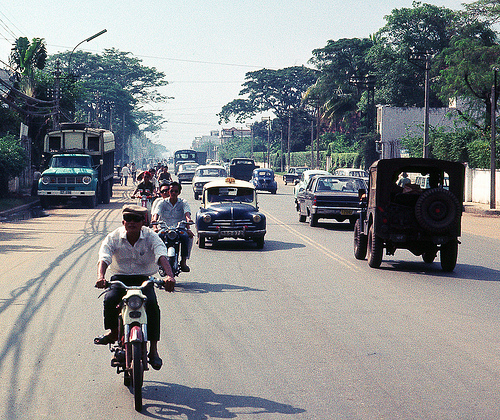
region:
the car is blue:
[220, 206, 236, 216]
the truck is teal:
[60, 165, 80, 170]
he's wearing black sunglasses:
[120, 210, 140, 222]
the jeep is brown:
[367, 190, 377, 200]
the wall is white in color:
[475, 175, 485, 190]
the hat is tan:
[120, 205, 140, 215]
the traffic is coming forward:
[112, 166, 238, 376]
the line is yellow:
[298, 227, 320, 249]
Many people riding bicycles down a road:
[92, 159, 200, 416]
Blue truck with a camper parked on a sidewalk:
[30, 126, 115, 205]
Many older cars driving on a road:
[171, 145, 473, 277]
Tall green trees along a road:
[12, 4, 492, 171]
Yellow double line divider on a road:
[250, 202, 369, 281]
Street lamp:
[64, 22, 112, 54]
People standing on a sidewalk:
[118, 156, 140, 183]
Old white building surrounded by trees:
[372, 99, 497, 151]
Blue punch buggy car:
[248, 166, 278, 192]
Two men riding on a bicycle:
[147, 178, 195, 276]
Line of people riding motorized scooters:
[100, 159, 190, 419]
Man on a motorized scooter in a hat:
[92, 202, 175, 413]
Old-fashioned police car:
[193, 173, 270, 248]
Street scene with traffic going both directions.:
[114, 144, 494, 409]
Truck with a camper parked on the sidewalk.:
[34, 115, 121, 215]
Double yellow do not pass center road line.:
[258, 202, 365, 284]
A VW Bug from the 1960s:
[249, 164, 279, 196]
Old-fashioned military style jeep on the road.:
[345, 155, 475, 272]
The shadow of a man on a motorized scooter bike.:
[119, 359, 313, 417]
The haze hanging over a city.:
[115, 90, 267, 186]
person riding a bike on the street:
[82, 192, 189, 408]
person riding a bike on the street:
[152, 174, 195, 294]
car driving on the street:
[185, 175, 267, 255]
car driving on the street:
[292, 172, 379, 226]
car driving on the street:
[287, 167, 336, 202]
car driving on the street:
[247, 165, 282, 196]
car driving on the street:
[175, 159, 205, 184]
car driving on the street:
[279, 164, 314, 188]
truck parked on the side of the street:
[31, 122, 126, 212]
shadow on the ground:
[181, 384, 236, 417]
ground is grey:
[284, 333, 387, 405]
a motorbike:
[118, 279, 163, 408]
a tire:
[126, 345, 152, 407]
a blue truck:
[43, 150, 108, 202]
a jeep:
[367, 165, 482, 272]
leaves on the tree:
[99, 58, 142, 91]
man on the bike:
[106, 205, 173, 278]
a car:
[286, 172, 358, 227]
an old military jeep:
[351, 159, 477, 279]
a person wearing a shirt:
[108, 206, 159, 288]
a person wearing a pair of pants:
[91, 273, 181, 373]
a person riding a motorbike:
[106, 206, 163, 401]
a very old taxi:
[198, 173, 268, 261]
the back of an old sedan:
[310, 178, 373, 220]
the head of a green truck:
[30, 145, 114, 210]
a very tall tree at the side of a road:
[231, 62, 329, 177]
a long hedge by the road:
[259, 153, 374, 177]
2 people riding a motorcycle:
[152, 183, 192, 238]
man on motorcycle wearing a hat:
[87, 196, 177, 408]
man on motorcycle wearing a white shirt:
[149, 182, 200, 288]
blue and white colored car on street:
[188, 172, 275, 253]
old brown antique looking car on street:
[348, 146, 470, 279]